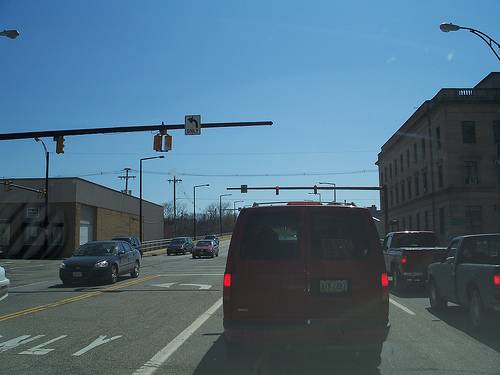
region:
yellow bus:
[225, 206, 382, 364]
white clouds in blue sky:
[40, 9, 101, 60]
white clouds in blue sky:
[54, 52, 98, 84]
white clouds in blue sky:
[141, 28, 182, 66]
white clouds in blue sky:
[257, 43, 338, 101]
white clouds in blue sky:
[332, 49, 380, 89]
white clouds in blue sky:
[321, 92, 361, 134]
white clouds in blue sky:
[272, 128, 316, 155]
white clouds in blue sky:
[77, 148, 102, 163]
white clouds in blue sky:
[350, 29, 410, 91]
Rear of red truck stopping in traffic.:
[213, 198, 401, 363]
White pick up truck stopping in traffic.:
[426, 230, 497, 332]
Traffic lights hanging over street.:
[226, 181, 325, 200]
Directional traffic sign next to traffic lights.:
[178, 109, 205, 138]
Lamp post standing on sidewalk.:
[136, 150, 167, 240]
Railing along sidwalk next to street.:
[143, 235, 163, 250]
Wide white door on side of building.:
[73, 203, 101, 247]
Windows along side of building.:
[388, 133, 430, 211]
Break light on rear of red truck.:
[217, 265, 240, 290]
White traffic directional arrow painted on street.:
[146, 275, 215, 300]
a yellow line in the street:
[42, 294, 71, 313]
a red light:
[221, 265, 233, 301]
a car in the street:
[60, 236, 143, 286]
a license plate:
[313, 277, 356, 295]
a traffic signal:
[231, 176, 376, 196]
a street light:
[194, 177, 211, 195]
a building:
[377, 143, 464, 222]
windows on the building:
[381, 150, 439, 196]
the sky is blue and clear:
[277, 67, 381, 141]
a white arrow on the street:
[156, 278, 215, 297]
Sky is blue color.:
[28, 12, 423, 95]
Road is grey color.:
[75, 290, 180, 330]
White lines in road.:
[30, 307, 225, 362]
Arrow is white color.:
[145, 270, 220, 300]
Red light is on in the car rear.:
[210, 245, 496, 305]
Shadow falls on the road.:
[55, 250, 490, 361]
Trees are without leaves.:
[157, 195, 237, 227]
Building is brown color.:
[365, 100, 495, 255]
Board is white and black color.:
[175, 105, 211, 145]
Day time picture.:
[16, 26, 488, 349]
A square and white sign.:
[175, 112, 210, 140]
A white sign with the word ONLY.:
[179, 110, 204, 137]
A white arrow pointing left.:
[143, 272, 218, 302]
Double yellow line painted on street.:
[6, 273, 173, 320]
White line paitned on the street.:
[164, 270, 211, 371]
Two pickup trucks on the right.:
[386, 216, 498, 339]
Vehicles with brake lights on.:
[221, 195, 398, 361]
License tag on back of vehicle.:
[315, 273, 355, 301]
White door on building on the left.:
[57, 183, 112, 257]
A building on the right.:
[368, 81, 498, 269]